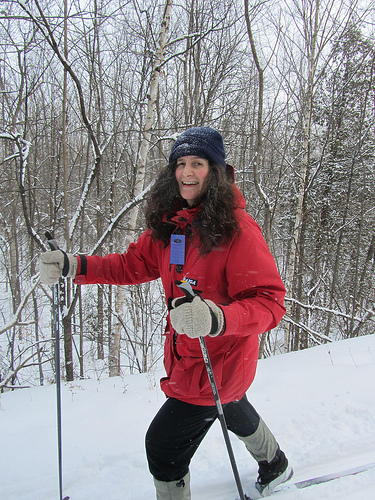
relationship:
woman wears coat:
[63, 115, 294, 492] [71, 183, 286, 396]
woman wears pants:
[63, 115, 294, 492] [144, 396, 284, 494]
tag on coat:
[173, 234, 185, 263] [71, 183, 286, 396]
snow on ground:
[7, 396, 63, 499] [10, 331, 375, 496]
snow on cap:
[7, 396, 63, 499] [171, 124, 230, 165]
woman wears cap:
[63, 115, 294, 492] [171, 124, 230, 165]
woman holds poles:
[63, 115, 294, 492] [31, 220, 251, 499]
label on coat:
[184, 276, 198, 290] [71, 183, 286, 396]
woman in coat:
[63, 115, 294, 492] [71, 183, 286, 396]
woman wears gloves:
[63, 115, 294, 492] [34, 243, 225, 336]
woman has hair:
[63, 115, 294, 492] [146, 163, 237, 245]